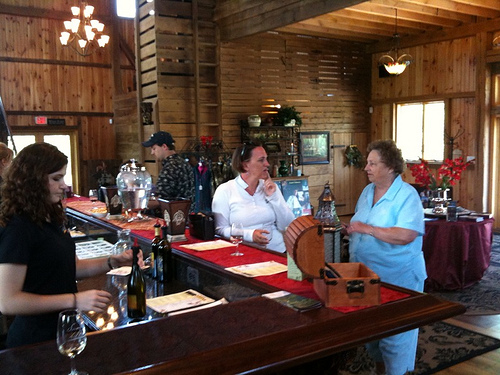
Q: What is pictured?
A: Restaurant.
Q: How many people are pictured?
A: 5.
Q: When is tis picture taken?
A: While dining.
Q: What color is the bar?
A: Brown.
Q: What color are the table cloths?
A: Red.